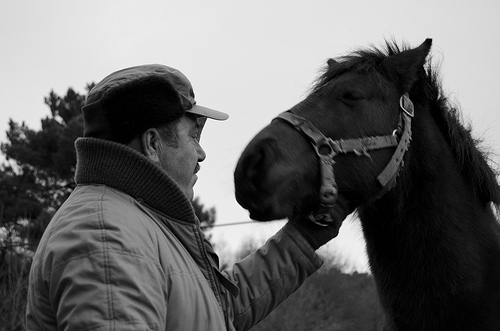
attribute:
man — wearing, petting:
[25, 62, 342, 329]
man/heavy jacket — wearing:
[21, 124, 268, 326]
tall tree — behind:
[29, 92, 81, 157]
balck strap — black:
[280, 103, 422, 183]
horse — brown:
[247, 33, 494, 329]